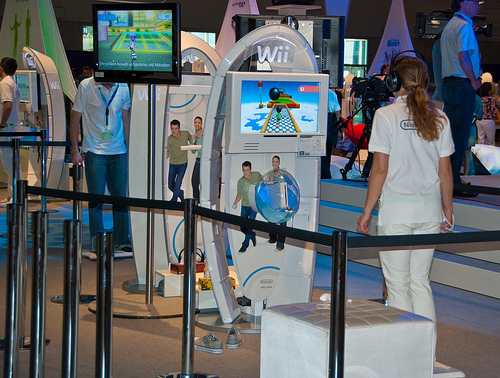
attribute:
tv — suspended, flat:
[92, 1, 180, 82]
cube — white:
[258, 291, 437, 377]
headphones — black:
[383, 50, 427, 95]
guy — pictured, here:
[70, 75, 134, 259]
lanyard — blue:
[97, 80, 119, 128]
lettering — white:
[257, 43, 291, 65]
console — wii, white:
[264, 180, 288, 212]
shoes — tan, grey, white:
[3, 197, 17, 207]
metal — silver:
[62, 217, 79, 377]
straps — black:
[30, 185, 499, 250]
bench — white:
[258, 298, 435, 377]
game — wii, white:
[226, 66, 329, 157]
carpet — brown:
[3, 253, 265, 377]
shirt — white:
[366, 94, 455, 363]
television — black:
[91, 3, 184, 88]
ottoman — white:
[259, 294, 435, 376]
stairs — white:
[323, 179, 499, 302]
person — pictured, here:
[440, 2, 482, 198]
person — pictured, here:
[358, 50, 454, 351]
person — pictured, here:
[326, 88, 338, 177]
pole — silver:
[94, 230, 110, 377]